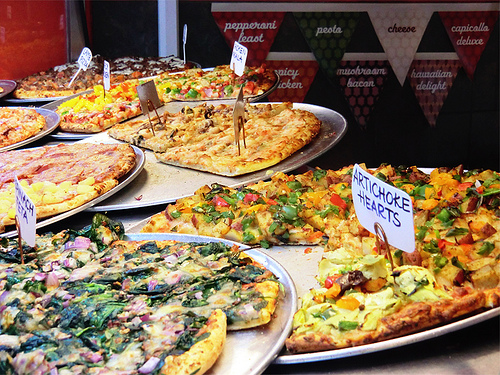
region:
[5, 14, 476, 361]
pizza pies on display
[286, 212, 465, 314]
an artichoke pizza pie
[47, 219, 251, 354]
a spinach pizza pie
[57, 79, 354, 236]
a silver round tray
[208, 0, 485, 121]
flags on the wall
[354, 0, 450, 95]
a white flag hanging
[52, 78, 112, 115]
the pineapple is yellow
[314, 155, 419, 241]
the letters are dark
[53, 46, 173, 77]
meat and cheese on the pizza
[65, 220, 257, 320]
the spinach is green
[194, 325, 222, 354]
part of a pizza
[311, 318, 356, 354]
edge of a pizza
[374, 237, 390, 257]
part of a metal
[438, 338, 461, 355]
part of a shade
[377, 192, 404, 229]
part of a letter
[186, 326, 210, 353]
part of a pizza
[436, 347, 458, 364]
part of a shade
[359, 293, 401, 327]
part of a pizza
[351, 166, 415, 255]
small white paper sign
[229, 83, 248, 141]
small white paper sign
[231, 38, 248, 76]
small white paper sign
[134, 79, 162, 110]
small white paper sign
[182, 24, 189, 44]
small white paper sign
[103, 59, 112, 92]
small white paper sign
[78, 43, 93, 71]
small white paper sign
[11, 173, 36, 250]
small white paper sign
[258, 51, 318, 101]
red colored plastic flag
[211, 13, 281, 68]
red colored plastic flag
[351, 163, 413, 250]
the sign that says "ARTICHOKE HEARTS"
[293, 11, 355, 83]
the flag that says "pesto"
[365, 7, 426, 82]
the flag that says "cheese"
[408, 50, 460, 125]
the flag that says "hawaiian delight"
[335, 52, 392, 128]
the flag that says "mushroom bacon"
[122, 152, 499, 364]
the pizza on a large round tray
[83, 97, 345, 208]
pizza slices on a large metal tray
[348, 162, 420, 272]
a sign standing up on the pizza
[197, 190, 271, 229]
the toppings on the pizza slice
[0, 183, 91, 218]
yellow toppings on a pizza slice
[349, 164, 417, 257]
The label says "Artichoke Hearts".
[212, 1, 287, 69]
The section of banner reads "Pepperoni Feast".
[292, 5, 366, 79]
The green banner segment reads "Pasta".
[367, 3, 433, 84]
The white banner section says "Cheese".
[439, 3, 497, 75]
The right red banner secton says "Capicalla Deluxe".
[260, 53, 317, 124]
The partially concealed red banner section says "Spicy Chicken".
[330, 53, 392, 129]
The bottom middle banner section says "Mushroom Bacon".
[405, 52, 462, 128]
The bottom right banner section says "Hawaiian Delight".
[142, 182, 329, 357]
A slice is missing from the Artichoke Heart pizza.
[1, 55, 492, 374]
The pizzas are on silver metal pans.